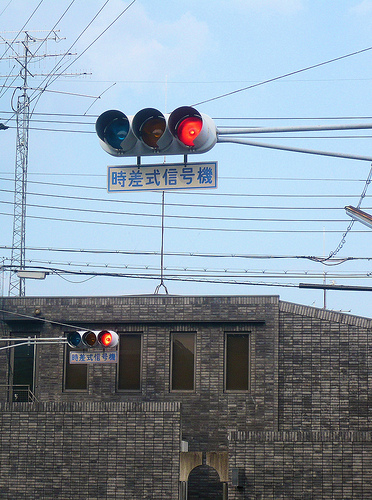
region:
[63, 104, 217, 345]
Stop lights are lit red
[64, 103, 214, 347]
Stop lights have three colors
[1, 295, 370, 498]
building is made of stone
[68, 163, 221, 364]
Street name signs under stop light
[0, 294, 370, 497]
Building is gray and brick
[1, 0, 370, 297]
Wires above building for electricity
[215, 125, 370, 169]
Metal pole holding closest stop light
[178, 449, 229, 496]
Archway made in wall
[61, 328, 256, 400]
Four rectangular building windows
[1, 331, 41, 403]
Railing and rectangular door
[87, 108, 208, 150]
gray light signal handing from wire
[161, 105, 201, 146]
gray light signal handing from wire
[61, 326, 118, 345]
gray light signal handing from wire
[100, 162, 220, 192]
blue and white sign hanging from signal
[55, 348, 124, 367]
blue and white sign hanging from signal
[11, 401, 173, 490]
gray and brown bricks of building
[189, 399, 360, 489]
gray and brown bricks of building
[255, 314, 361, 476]
gray and brown bricks of building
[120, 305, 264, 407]
gray and brown bricks of building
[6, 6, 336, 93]
gray wires against white clouds and blue sky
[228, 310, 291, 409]
the window is glass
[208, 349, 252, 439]
the window is glass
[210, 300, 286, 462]
the window is glass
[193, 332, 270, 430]
the window is glass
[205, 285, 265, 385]
the window is glass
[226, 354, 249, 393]
the window is glass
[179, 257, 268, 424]
the window is glass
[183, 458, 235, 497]
The entrance to the building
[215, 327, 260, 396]
windows of the brick building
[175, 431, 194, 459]
Entrance light of the building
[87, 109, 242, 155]
Traffic signal on a pole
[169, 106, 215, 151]
Red light on the traffic signal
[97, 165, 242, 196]
Street sign identification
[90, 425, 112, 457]
Bricks on the building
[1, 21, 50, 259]
Antenna that is on the top of the building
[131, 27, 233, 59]
Clouds in the sky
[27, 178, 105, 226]
Telephone and electrical wires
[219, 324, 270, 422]
the window is tinted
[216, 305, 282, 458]
the window is tinted